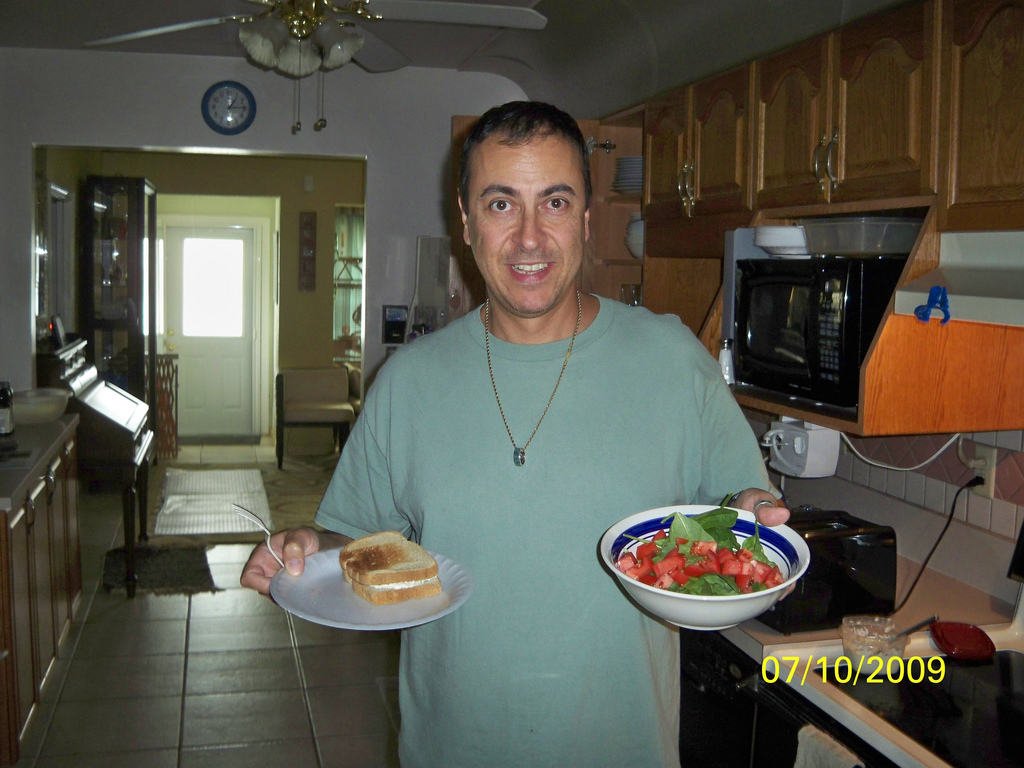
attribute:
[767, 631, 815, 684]
number — yellow , print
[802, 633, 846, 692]
number — print, yellow 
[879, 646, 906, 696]
number — yellow , print 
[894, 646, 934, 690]
number — print , yellow 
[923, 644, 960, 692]
number — yellow , print 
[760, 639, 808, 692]
numbers — yellow , print 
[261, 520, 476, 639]
plate — white 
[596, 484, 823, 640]
bowl — white 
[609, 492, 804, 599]
stripe — blue 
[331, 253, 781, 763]
t-shirt — green 